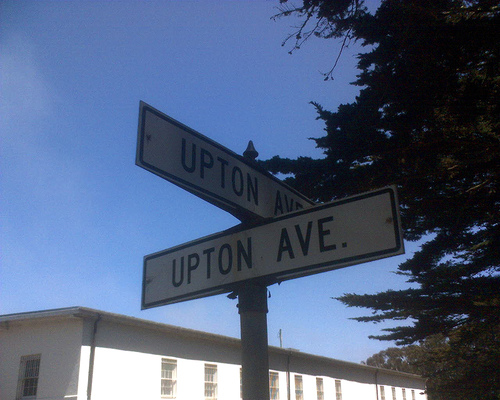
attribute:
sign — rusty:
[140, 182, 409, 308]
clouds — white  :
[1, 89, 82, 144]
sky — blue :
[5, 1, 397, 361]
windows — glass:
[146, 367, 233, 398]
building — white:
[10, 300, 499, 397]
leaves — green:
[263, 2, 498, 389]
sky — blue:
[88, 22, 158, 74]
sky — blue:
[10, 98, 70, 158]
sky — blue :
[71, 12, 264, 104]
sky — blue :
[53, 69, 188, 94]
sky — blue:
[55, 158, 95, 224]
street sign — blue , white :
[139, 201, 375, 301]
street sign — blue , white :
[135, 99, 324, 221]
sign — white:
[79, 124, 321, 274]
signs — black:
[135, 95, 404, 310]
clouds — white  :
[1, 21, 53, 126]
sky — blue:
[1, 2, 498, 364]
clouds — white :
[5, 31, 148, 231]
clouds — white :
[25, 163, 144, 279]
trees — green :
[223, 3, 497, 399]